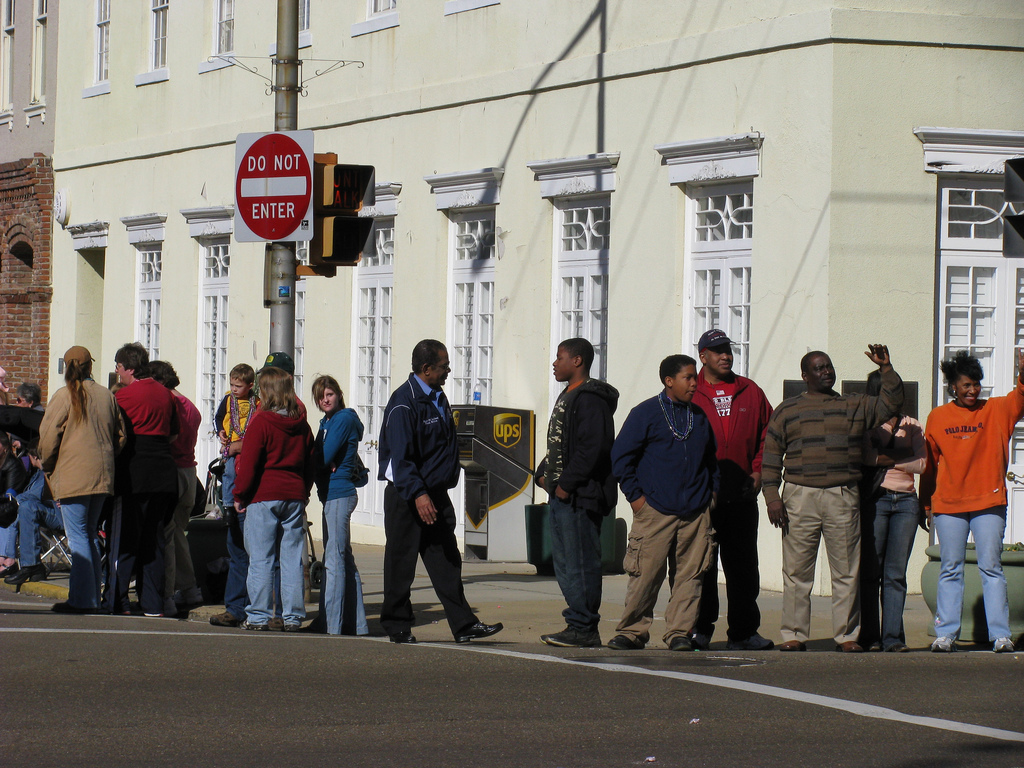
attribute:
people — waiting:
[14, 338, 1010, 655]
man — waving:
[763, 343, 903, 649]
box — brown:
[451, 403, 536, 564]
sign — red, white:
[241, 131, 315, 243]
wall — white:
[1, 2, 1021, 596]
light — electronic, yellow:
[315, 152, 374, 275]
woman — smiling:
[237, 364, 318, 636]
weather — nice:
[5, 2, 1019, 762]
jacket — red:
[688, 367, 783, 475]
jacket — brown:
[35, 378, 133, 505]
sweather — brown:
[761, 373, 910, 483]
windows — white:
[695, 190, 748, 385]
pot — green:
[924, 543, 1022, 649]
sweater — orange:
[924, 388, 1022, 515]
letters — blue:
[943, 422, 994, 437]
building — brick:
[3, 167, 48, 419]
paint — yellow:
[5, 574, 73, 599]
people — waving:
[756, 345, 1013, 663]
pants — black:
[381, 481, 491, 642]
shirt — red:
[701, 375, 743, 432]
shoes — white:
[937, 634, 1022, 655]